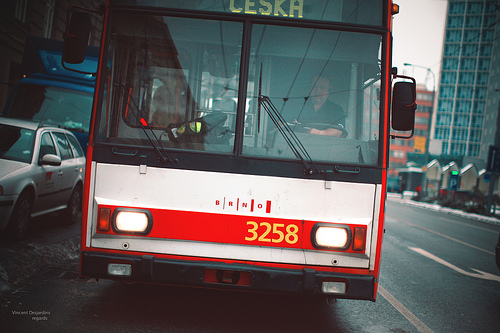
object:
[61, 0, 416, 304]
bus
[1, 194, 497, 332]
street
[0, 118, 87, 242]
car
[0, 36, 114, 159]
truck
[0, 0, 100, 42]
buildings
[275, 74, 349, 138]
man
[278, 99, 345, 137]
shirt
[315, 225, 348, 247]
headlights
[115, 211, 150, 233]
headlights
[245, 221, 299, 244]
numbers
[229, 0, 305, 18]
sign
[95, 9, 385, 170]
windshield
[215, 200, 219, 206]
letters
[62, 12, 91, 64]
mirror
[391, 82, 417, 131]
mirror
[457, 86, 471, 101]
window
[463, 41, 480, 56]
window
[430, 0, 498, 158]
building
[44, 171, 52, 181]
decal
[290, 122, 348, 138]
wheel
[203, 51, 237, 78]
mirror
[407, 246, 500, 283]
marking